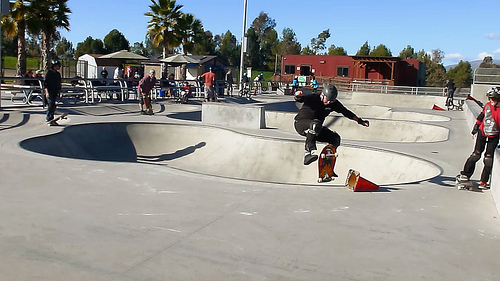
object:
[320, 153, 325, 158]
wheel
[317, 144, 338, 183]
skateboard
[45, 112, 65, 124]
edge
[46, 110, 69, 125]
skateboard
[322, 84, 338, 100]
helmet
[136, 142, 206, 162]
shadow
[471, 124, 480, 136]
glove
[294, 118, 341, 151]
trouser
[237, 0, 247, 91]
post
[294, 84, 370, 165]
skater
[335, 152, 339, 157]
wheel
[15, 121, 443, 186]
bowl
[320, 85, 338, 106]
head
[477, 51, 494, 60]
cloud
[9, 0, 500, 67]
sky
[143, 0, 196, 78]
tree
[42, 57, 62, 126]
skater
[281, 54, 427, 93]
building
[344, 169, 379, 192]
cone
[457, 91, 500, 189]
skater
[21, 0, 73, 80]
tree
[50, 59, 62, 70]
helmet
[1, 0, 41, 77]
tree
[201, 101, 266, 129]
ramp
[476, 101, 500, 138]
shirt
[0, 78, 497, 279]
park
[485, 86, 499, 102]
helmet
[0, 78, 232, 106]
benches